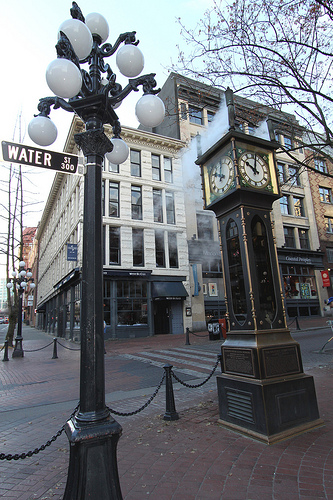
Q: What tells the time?
A: A clock.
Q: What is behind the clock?
A: Buildings.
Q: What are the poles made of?
A: Metal.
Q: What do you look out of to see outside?
A: A window.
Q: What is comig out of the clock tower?
A: Smoke.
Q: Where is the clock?
A: On the sidewalk.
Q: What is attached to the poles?
A: A chain.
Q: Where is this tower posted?
A: To base.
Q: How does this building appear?
A: White in color.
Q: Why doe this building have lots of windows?
A: For natural lighting.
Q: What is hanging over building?
A: Tree branches.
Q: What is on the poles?
A: Lights.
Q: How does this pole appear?
A: Black.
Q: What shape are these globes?
A: Round.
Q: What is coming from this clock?
A: Steam.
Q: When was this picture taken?
A: Daytime.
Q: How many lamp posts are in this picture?
A: 1.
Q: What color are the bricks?
A: Red.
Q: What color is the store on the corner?
A: White.